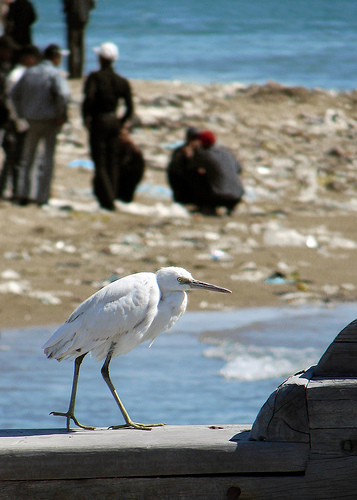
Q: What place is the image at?
A: It is at the beach.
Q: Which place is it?
A: It is a beach.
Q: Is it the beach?
A: Yes, it is the beach.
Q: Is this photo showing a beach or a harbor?
A: It is showing a beach.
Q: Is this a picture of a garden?
A: No, the picture is showing a beach.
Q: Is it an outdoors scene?
A: Yes, it is outdoors.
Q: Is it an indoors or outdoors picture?
A: It is outdoors.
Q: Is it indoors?
A: No, it is outdoors.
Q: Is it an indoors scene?
A: No, it is outdoors.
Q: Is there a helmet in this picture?
A: No, there are no helmets.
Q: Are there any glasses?
A: No, there are no glasses.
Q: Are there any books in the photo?
A: No, there are no books.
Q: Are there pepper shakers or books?
A: No, there are no books or pepper shakers.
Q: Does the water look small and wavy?
A: Yes, the water is small and wavy.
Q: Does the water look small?
A: Yes, the water is small.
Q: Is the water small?
A: Yes, the water is small.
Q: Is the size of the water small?
A: Yes, the water is small.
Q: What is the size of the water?
A: The water is small.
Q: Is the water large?
A: No, the water is small.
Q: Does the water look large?
A: No, the water is small.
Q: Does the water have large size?
A: No, the water is small.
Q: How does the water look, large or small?
A: The water is small.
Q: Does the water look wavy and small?
A: Yes, the water is wavy and small.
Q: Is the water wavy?
A: Yes, the water is wavy.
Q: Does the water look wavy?
A: Yes, the water is wavy.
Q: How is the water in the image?
A: The water is wavy.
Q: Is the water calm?
A: No, the water is wavy.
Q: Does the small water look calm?
A: No, the water is wavy.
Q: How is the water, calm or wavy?
A: The water is wavy.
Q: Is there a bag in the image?
A: No, there are no bags.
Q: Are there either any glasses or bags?
A: No, there are no bags or glasses.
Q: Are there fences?
A: Yes, there is a fence.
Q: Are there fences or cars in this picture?
A: Yes, there is a fence.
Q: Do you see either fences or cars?
A: Yes, there is a fence.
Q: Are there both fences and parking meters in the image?
A: No, there is a fence but no parking meters.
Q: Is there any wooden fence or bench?
A: Yes, there is a wood fence.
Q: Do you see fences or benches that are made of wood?
A: Yes, the fence is made of wood.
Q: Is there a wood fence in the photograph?
A: Yes, there is a wood fence.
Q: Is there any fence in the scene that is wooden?
A: Yes, there is a fence that is wooden.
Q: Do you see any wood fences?
A: Yes, there is a fence that is made of wood.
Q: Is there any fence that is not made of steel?
A: Yes, there is a fence that is made of wood.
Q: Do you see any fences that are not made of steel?
A: Yes, there is a fence that is made of wood.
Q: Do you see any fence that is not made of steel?
A: Yes, there is a fence that is made of wood.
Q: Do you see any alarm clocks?
A: No, there are no alarm clocks.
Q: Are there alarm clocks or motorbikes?
A: No, there are no alarm clocks or motorbikes.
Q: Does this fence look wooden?
A: Yes, the fence is wooden.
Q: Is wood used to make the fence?
A: Yes, the fence is made of wood.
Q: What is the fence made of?
A: The fence is made of wood.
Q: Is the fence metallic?
A: No, the fence is wooden.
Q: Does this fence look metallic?
A: No, the fence is wooden.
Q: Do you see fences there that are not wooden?
A: No, there is a fence but it is wooden.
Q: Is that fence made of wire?
A: No, the fence is made of wood.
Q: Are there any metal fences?
A: No, there is a fence but it is made of wood.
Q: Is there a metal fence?
A: No, there is a fence but it is made of wood.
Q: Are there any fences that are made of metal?
A: No, there is a fence but it is made of wood.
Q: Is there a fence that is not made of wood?
A: No, there is a fence but it is made of wood.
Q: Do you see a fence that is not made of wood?
A: No, there is a fence but it is made of wood.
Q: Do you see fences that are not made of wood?
A: No, there is a fence but it is made of wood.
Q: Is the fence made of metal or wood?
A: The fence is made of wood.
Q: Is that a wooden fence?
A: Yes, that is a wooden fence.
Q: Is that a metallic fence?
A: No, that is a wooden fence.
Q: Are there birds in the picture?
A: Yes, there is a bird.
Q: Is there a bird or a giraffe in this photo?
A: Yes, there is a bird.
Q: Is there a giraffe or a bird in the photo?
A: Yes, there is a bird.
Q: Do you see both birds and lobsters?
A: No, there is a bird but no lobsters.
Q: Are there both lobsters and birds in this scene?
A: No, there is a bird but no lobsters.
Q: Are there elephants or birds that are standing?
A: Yes, the bird is standing.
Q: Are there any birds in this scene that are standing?
A: Yes, there is a bird that is standing.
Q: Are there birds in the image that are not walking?
A: Yes, there is a bird that is standing.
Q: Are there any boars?
A: No, there are no boars.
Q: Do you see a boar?
A: No, there are no boars.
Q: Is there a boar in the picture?
A: No, there are no boars.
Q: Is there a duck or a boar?
A: No, there are no boars or ducks.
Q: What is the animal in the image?
A: The animal is a bird.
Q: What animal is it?
A: The animal is a bird.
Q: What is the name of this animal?
A: This is a bird.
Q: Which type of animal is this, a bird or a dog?
A: This is a bird.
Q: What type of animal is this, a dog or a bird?
A: This is a bird.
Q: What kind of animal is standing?
A: The animal is a bird.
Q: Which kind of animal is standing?
A: The animal is a bird.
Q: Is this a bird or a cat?
A: This is a bird.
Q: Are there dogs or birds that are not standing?
A: No, there is a bird but it is standing.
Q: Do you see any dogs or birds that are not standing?
A: No, there is a bird but it is standing.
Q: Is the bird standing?
A: Yes, the bird is standing.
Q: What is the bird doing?
A: The bird is standing.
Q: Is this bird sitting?
A: No, the bird is standing.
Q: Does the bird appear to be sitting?
A: No, the bird is standing.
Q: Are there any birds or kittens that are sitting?
A: No, there is a bird but it is standing.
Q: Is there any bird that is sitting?
A: No, there is a bird but it is standing.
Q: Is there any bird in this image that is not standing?
A: No, there is a bird but it is standing.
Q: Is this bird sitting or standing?
A: The bird is standing.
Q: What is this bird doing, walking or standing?
A: The bird is standing.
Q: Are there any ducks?
A: No, there are no ducks.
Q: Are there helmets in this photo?
A: No, there are no helmets.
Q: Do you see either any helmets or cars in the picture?
A: No, there are no helmets or cars.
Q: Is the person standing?
A: Yes, the person is standing.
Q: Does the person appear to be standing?
A: Yes, the person is standing.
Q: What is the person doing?
A: The person is standing.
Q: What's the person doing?
A: The person is standing.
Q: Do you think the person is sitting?
A: No, the person is standing.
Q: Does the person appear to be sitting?
A: No, the person is standing.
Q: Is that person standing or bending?
A: The person is standing.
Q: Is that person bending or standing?
A: The person is standing.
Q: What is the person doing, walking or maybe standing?
A: The person is standing.